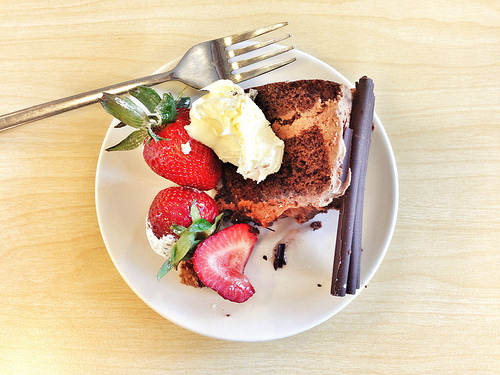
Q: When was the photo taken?
A: During the day.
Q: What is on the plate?
A: Food.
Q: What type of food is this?
A: Cake.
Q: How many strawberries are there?
A: Three.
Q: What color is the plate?
A: White.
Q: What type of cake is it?
A: Chocolate.